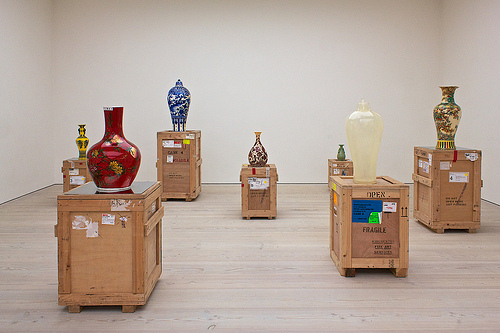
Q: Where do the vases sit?
A: Crates.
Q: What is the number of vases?
A: Seven.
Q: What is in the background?
A: White walls.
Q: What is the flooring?
A: Light wood.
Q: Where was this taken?
A: Maybe an art gallery.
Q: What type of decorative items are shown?
A: Vases.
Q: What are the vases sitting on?
A: Crates.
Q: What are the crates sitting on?
A: Floor.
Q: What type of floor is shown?
A: Wooden.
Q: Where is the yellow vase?
A: Back left corner.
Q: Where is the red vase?
A: Front left.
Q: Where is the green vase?
A: Back right.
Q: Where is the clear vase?
A: Front right.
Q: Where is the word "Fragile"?
A: On the crate under the clear vase.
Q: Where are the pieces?
A: On the boxes.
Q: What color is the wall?
A: White.